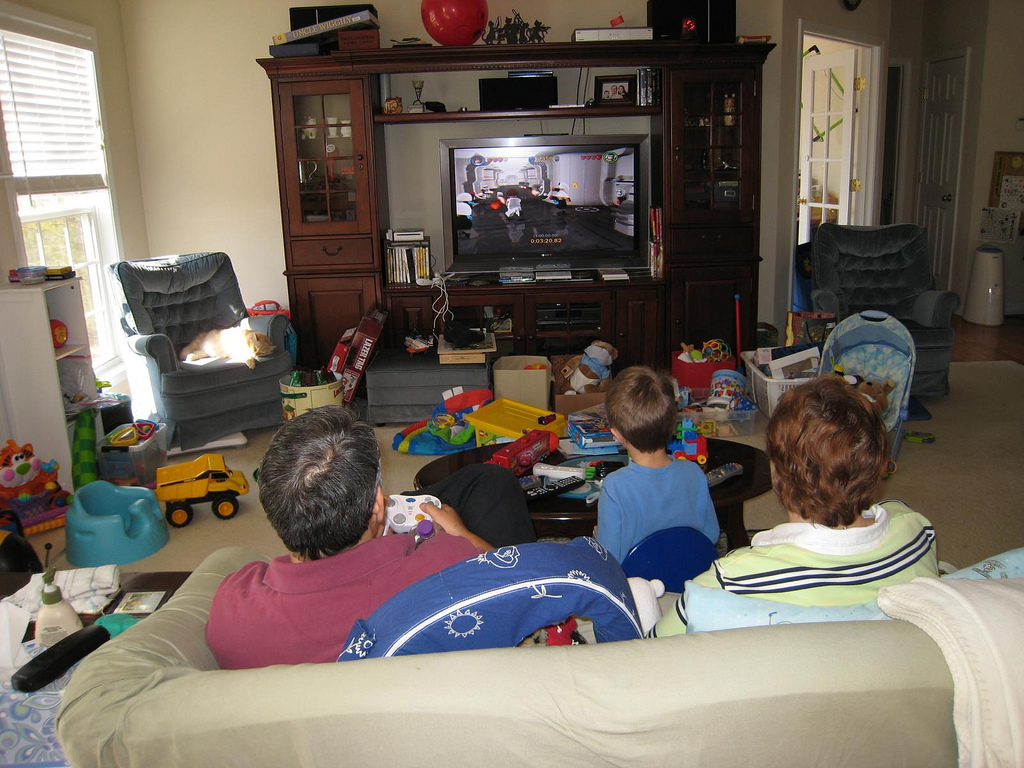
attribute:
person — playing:
[686, 365, 947, 601]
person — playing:
[578, 352, 718, 553]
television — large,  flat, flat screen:
[440, 130, 646, 270]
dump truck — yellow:
[151, 450, 257, 527]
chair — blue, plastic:
[619, 529, 714, 574]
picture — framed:
[592, 74, 644, 104]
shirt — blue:
[584, 455, 727, 561]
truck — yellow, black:
[149, 455, 252, 535]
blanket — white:
[880, 568, 1018, 765]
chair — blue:
[65, 476, 160, 568]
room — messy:
[5, 11, 1011, 759]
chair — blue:
[798, 216, 954, 412]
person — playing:
[191, 407, 485, 668]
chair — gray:
[111, 252, 309, 442]